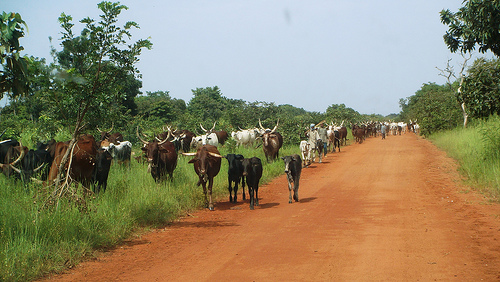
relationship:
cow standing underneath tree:
[48, 129, 113, 191] [42, 1, 154, 205]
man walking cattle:
[381, 124, 386, 140] [8, 115, 420, 211]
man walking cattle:
[308, 118, 316, 164] [8, 115, 420, 211]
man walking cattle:
[313, 115, 327, 158] [8, 115, 420, 211]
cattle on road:
[49, 107, 403, 199] [344, 133, 439, 271]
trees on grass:
[3, 13, 142, 126] [41, 161, 171, 228]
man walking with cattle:
[378, 121, 388, 139] [353, 126, 367, 143]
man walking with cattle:
[378, 121, 388, 139] [369, 125, 379, 140]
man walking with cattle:
[378, 121, 388, 139] [325, 124, 338, 151]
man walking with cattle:
[378, 121, 388, 139] [298, 135, 310, 164]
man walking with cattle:
[378, 121, 388, 139] [280, 152, 303, 206]